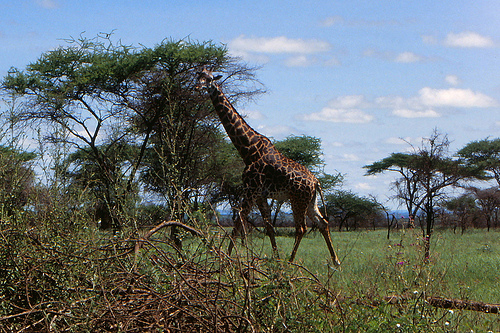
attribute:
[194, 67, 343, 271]
giraffe — wild, tan, spotted, walking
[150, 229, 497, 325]
grass — green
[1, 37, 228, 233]
tree — leafy, green, bare, flat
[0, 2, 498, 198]
sky — blue, cloudy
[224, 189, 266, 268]
leg — long, tan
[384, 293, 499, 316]
wood — brown